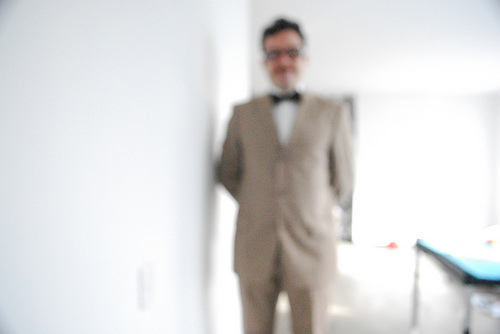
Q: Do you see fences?
A: No, there are no fences.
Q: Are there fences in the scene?
A: No, there are no fences.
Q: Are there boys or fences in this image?
A: No, there are no fences or boys.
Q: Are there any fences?
A: No, there are no fences.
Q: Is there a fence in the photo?
A: No, there are no fences.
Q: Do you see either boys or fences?
A: No, there are no fences or boys.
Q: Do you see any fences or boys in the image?
A: No, there are no fences or boys.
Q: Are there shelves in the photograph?
A: No, there are no shelves.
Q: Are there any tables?
A: Yes, there is a table.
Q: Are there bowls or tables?
A: Yes, there is a table.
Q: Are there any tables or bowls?
A: Yes, there is a table.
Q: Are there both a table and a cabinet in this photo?
A: No, there is a table but no cabinets.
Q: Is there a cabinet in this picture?
A: No, there are no cabinets.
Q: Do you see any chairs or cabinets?
A: No, there are no cabinets or chairs.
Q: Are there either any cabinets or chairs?
A: No, there are no cabinets or chairs.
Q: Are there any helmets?
A: No, there are no helmets.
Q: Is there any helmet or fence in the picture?
A: No, there are no helmets or fences.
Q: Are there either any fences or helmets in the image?
A: No, there are no helmets or fences.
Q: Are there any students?
A: No, there are no students.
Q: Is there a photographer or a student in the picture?
A: No, there are no students or photographers.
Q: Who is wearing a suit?
A: The man is wearing a suit.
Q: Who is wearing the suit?
A: The man is wearing a suit.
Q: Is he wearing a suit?
A: Yes, the man is wearing a suit.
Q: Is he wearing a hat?
A: No, the man is wearing a suit.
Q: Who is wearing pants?
A: The man is wearing pants.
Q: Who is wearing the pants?
A: The man is wearing pants.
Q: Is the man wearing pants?
A: Yes, the man is wearing pants.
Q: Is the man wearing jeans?
A: No, the man is wearing pants.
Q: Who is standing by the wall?
A: The man is standing by the wall.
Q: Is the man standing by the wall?
A: Yes, the man is standing by the wall.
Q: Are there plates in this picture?
A: No, there are no plates.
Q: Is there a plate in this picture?
A: No, there are no plates.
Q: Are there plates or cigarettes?
A: No, there are no plates or cigarettes.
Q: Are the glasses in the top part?
A: Yes, the glasses are in the top of the image.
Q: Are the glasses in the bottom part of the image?
A: No, the glasses are in the top of the image.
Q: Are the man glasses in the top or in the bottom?
A: The glasses are in the top of the image.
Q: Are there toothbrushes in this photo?
A: No, there are no toothbrushes.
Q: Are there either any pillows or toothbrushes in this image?
A: No, there are no toothbrushes or pillows.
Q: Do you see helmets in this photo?
A: No, there are no helmets.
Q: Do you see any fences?
A: No, there are no fences.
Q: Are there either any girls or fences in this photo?
A: No, there are no fences or girls.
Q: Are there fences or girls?
A: No, there are no fences or girls.